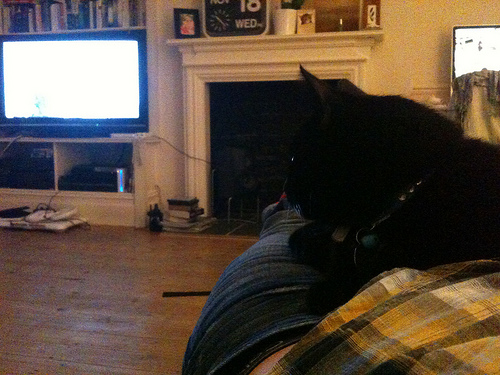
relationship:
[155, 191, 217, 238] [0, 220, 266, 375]
books on floor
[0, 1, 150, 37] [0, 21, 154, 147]
books near television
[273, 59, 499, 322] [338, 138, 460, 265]
cat has collar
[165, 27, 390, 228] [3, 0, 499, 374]
fireplace in room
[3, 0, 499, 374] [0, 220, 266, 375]
room has floor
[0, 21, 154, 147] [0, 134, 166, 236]
television has stand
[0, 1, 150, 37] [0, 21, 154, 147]
books behind television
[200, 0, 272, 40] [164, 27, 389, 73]
clock on mantle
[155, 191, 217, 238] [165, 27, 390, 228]
books near fireplace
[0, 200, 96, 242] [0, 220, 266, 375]
items on floor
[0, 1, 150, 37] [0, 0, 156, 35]
books on bookshelf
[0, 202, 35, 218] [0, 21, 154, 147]
remote to television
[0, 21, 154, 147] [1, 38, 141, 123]
television has screen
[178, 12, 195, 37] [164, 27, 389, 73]
picture on mantle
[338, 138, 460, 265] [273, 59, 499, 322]
collar on cat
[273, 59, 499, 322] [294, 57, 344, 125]
cat has ear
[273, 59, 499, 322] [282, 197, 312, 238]
cat has whiskers